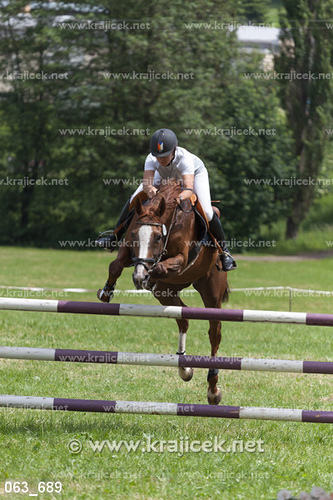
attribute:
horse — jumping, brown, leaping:
[95, 170, 261, 445]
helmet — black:
[118, 115, 225, 186]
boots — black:
[76, 183, 290, 272]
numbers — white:
[3, 467, 53, 496]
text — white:
[8, 69, 77, 82]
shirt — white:
[124, 156, 238, 201]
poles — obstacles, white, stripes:
[16, 284, 315, 459]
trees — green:
[49, 38, 141, 230]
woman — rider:
[108, 100, 236, 290]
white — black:
[119, 199, 166, 281]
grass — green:
[23, 302, 171, 394]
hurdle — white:
[110, 206, 180, 265]